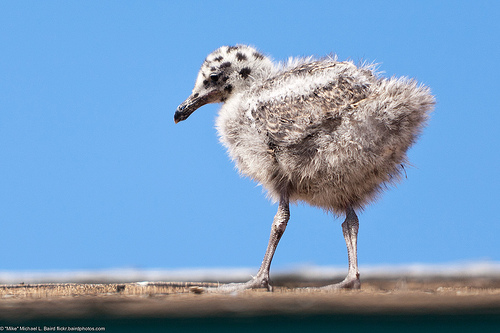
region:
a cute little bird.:
[127, 11, 454, 309]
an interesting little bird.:
[96, 19, 464, 302]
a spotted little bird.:
[129, 33, 449, 290]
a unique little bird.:
[110, 39, 463, 292]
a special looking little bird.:
[125, 6, 481, 298]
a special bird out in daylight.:
[119, 21, 456, 291]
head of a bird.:
[145, 38, 264, 123]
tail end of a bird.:
[358, 66, 441, 196]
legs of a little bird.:
[219, 204, 389, 301]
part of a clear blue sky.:
[15, 25, 157, 250]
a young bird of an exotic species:
[173, 32, 458, 299]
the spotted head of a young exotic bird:
[162, 39, 271, 129]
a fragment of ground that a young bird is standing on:
[0, 277, 232, 305]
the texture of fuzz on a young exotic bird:
[257, 84, 393, 179]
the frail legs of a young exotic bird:
[248, 204, 380, 291]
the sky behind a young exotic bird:
[30, 40, 164, 236]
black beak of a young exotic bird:
[163, 87, 211, 126]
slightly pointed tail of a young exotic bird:
[376, 77, 449, 155]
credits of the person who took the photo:
[1, 315, 101, 332]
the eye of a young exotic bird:
[205, 67, 227, 86]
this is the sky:
[33, 89, 134, 249]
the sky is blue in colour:
[51, 104, 168, 251]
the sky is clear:
[35, 82, 142, 225]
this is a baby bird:
[168, 31, 416, 287]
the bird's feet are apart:
[251, 207, 366, 279]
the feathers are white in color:
[243, 88, 388, 160]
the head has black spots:
[224, 50, 263, 84]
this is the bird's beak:
[173, 92, 212, 122]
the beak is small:
[172, 95, 210, 125]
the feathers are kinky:
[313, 114, 388, 181]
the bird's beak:
[160, 85, 212, 127]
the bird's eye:
[190, 62, 230, 89]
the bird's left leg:
[247, 159, 303, 304]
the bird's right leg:
[325, 201, 374, 299]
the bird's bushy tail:
[357, 70, 436, 159]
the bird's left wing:
[247, 58, 373, 146]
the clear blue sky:
[32, 47, 159, 229]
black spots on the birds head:
[204, 33, 271, 100]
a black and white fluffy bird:
[164, 21, 450, 307]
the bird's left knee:
[254, 206, 306, 243]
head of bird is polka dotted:
[165, 39, 287, 131]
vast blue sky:
[0, 1, 194, 273]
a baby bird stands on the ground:
[165, 38, 432, 295]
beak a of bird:
[166, 87, 210, 125]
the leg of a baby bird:
[241, 177, 289, 299]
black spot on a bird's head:
[237, 65, 254, 77]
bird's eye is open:
[207, 68, 223, 83]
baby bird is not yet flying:
[167, 37, 444, 292]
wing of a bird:
[259, 60, 377, 156]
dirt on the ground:
[1, 275, 208, 308]